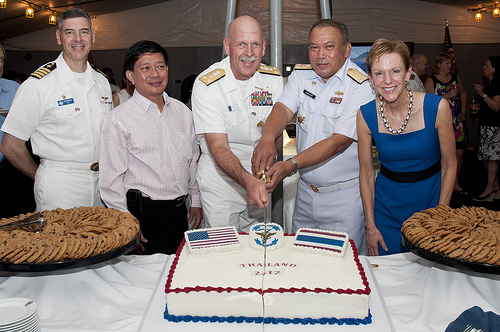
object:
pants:
[126, 186, 192, 254]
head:
[220, 12, 267, 78]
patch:
[199, 67, 229, 87]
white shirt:
[191, 55, 285, 156]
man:
[250, 17, 367, 252]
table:
[0, 241, 499, 331]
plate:
[399, 227, 499, 277]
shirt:
[0, 52, 119, 165]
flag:
[291, 226, 350, 255]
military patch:
[31, 63, 58, 80]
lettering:
[237, 261, 298, 268]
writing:
[249, 269, 284, 276]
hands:
[243, 177, 273, 210]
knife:
[256, 166, 271, 270]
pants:
[33, 165, 109, 217]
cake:
[160, 222, 375, 326]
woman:
[356, 37, 457, 254]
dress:
[359, 92, 443, 258]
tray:
[4, 234, 147, 276]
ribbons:
[249, 90, 274, 105]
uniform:
[1, 50, 115, 212]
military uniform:
[190, 56, 285, 230]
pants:
[291, 176, 369, 251]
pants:
[194, 163, 276, 231]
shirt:
[102, 86, 203, 219]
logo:
[247, 221, 285, 249]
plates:
[0, 296, 42, 327]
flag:
[183, 225, 239, 251]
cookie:
[24, 245, 47, 263]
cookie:
[447, 248, 466, 259]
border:
[163, 230, 373, 295]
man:
[188, 12, 288, 230]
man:
[98, 39, 202, 254]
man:
[0, 7, 121, 216]